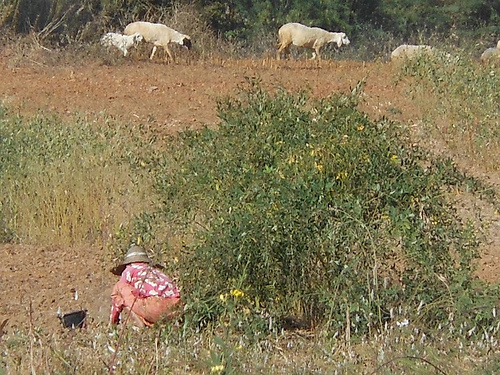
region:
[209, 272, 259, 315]
yellow wildflower growing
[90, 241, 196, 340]
a woman bending down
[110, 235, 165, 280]
a women's hat to block the sun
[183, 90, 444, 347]
a green bush growing wildflowers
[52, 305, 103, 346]
a black bucket next to the woman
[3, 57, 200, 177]
dead grass and dirt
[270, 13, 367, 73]
white sheep walking across the field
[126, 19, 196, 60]
a white sheep with a black head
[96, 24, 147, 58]
a baby sheep walking alongside its mother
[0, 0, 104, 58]
dead bushes and twigs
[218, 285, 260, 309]
tiny yellow flowers in field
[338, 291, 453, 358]
white flower budd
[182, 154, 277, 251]
large path of gren bush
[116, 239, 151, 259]
white band around green hat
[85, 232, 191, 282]
large green hat with lining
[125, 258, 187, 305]
red and white scarf around woman's back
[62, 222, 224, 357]
woman crouching on the ground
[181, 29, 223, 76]
black face on white animal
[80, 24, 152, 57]
small white animal walking on dirt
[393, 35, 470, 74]
large rock boulder on side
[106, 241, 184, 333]
a woman kneeling down by a bush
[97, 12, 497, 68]
some sheep walking along a path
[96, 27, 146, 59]
a lamb walking next to its mom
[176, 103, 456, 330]
a big leafy bush in the middle of a field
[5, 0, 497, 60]
a line of trees in the background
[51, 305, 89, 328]
a bucket on the ground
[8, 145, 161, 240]
some tall dried grass in front of a bush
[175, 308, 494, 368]
some plants with little flowers on them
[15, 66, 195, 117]
a big patch of dirt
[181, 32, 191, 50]
the face with black fur on it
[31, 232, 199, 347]
a migrant worker working in a field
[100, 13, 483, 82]
a line of white sheep crossing the edge of the field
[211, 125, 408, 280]
a green dense brush area in the field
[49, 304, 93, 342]
a black pail the worker is using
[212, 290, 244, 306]
some yellow flowers growing in the field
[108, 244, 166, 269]
a brown wide-brimmed hat the worker is wearing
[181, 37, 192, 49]
the black face of one of the sheep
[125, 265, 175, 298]
red and white patterned shirt the worker is wearing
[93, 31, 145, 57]
a smaller baby sheep walking with it's mother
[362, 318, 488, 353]
some wispy white flowers growing in the field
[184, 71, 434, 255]
A bush is visible.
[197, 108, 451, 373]
A bush is visible.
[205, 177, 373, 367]
A bush is visible.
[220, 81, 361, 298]
A bush is visible.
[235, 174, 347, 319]
A bush is visible.